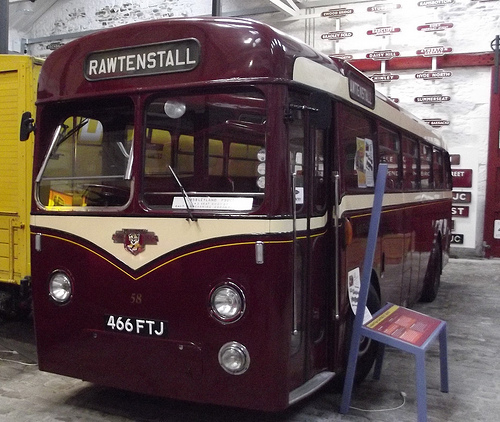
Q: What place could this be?
A: It is a garage.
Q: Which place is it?
A: It is a garage.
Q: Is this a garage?
A: Yes, it is a garage.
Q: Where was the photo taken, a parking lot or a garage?
A: It was taken at a garage.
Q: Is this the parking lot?
A: No, it is the garage.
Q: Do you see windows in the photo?
A: Yes, there is a window.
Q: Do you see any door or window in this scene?
A: Yes, there is a window.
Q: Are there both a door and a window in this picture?
A: Yes, there are both a window and a door.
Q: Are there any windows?
A: Yes, there is a window.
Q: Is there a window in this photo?
A: Yes, there is a window.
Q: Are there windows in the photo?
A: Yes, there is a window.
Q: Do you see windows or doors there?
A: Yes, there is a window.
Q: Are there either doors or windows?
A: Yes, there is a window.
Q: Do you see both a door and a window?
A: Yes, there are both a window and a door.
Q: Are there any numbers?
A: Yes, there are numbers.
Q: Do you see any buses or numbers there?
A: Yes, there are numbers.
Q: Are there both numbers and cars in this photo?
A: Yes, there are both numbers and a car.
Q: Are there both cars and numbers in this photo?
A: Yes, there are both numbers and a car.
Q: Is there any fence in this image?
A: No, there are no fences.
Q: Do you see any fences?
A: No, there are no fences.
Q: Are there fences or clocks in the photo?
A: No, there are no fences or clocks.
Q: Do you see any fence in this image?
A: No, there are no fences.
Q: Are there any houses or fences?
A: No, there are no fences or houses.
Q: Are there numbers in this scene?
A: Yes, there are numbers.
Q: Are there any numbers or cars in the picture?
A: Yes, there are numbers.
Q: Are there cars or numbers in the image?
A: Yes, there are numbers.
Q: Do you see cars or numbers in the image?
A: Yes, there are numbers.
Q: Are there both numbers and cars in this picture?
A: Yes, there are both numbers and a car.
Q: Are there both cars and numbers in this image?
A: Yes, there are both numbers and a car.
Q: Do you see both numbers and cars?
A: Yes, there are both numbers and a car.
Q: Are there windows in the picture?
A: Yes, there are windows.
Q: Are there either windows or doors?
A: Yes, there are windows.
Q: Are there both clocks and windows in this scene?
A: No, there are windows but no clocks.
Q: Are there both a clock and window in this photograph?
A: No, there are windows but no clocks.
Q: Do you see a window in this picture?
A: Yes, there are windows.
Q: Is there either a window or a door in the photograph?
A: Yes, there are windows.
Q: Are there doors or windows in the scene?
A: Yes, there are windows.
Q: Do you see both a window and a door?
A: Yes, there are both a window and a door.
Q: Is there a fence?
A: No, there are no fences.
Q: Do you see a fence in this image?
A: No, there are no fences.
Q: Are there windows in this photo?
A: Yes, there are windows.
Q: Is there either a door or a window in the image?
A: Yes, there are windows.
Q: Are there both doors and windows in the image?
A: Yes, there are both windows and a door.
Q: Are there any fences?
A: No, there are no fences.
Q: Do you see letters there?
A: Yes, there are letters.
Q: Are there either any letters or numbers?
A: Yes, there are letters.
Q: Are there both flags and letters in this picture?
A: No, there are letters but no flags.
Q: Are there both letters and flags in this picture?
A: No, there are letters but no flags.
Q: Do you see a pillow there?
A: No, there are no pillows.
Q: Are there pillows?
A: No, there are no pillows.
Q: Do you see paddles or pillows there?
A: No, there are no pillows or paddles.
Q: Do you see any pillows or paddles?
A: No, there are no pillows or paddles.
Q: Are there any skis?
A: No, there are no skis.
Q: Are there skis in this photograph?
A: No, there are no skis.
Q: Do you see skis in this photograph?
A: No, there are no skis.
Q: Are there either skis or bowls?
A: No, there are no skis or bowls.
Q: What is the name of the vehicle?
A: The vehicle is a car.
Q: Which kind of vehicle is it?
A: The vehicle is a car.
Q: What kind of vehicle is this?
A: That is a car.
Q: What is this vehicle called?
A: That is a car.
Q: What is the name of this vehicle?
A: That is a car.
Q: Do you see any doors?
A: Yes, there is a door.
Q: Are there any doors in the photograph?
A: Yes, there is a door.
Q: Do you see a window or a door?
A: Yes, there is a door.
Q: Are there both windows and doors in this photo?
A: Yes, there are both a door and a window.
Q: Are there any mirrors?
A: Yes, there is a mirror.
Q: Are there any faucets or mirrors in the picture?
A: Yes, there is a mirror.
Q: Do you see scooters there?
A: No, there are no scooters.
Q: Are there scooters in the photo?
A: No, there are no scooters.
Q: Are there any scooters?
A: No, there are no scooters.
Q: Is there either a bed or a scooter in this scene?
A: No, there are no scooters or beds.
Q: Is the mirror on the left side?
A: Yes, the mirror is on the left of the image.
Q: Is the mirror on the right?
A: No, the mirror is on the left of the image.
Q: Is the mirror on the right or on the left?
A: The mirror is on the left of the image.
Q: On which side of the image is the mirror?
A: The mirror is on the left of the image.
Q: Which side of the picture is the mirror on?
A: The mirror is on the left of the image.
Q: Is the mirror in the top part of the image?
A: Yes, the mirror is in the top of the image.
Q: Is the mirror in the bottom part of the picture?
A: No, the mirror is in the top of the image.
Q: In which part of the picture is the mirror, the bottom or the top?
A: The mirror is in the top of the image.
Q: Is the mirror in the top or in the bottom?
A: The mirror is in the top of the image.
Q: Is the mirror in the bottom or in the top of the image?
A: The mirror is in the top of the image.